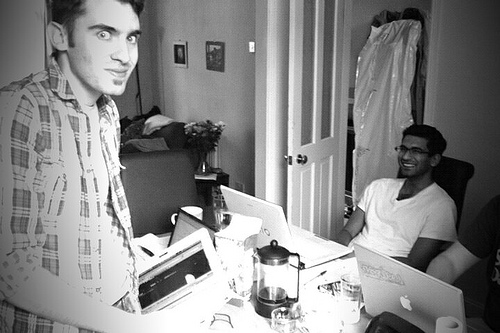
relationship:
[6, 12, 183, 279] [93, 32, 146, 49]
man has eye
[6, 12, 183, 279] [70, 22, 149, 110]
man has face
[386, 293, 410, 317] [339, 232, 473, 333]
apple on computer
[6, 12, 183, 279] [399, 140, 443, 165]
man with glasses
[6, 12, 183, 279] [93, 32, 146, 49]
man with eye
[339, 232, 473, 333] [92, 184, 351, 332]
computer on table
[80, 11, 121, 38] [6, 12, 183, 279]
head of man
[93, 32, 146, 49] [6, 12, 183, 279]
eye of man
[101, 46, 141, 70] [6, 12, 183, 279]
nose of man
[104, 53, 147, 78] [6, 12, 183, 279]
lip of man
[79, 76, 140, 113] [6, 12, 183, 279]
chin of man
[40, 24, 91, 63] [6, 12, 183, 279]
ear of man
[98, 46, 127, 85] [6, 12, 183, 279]
cheek of man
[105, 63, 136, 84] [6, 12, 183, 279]
teeth of man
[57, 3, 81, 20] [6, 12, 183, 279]
hair of man